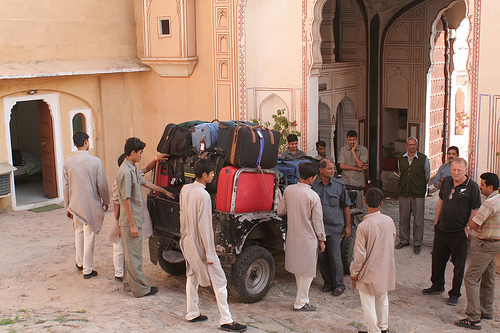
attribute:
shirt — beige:
[468, 188, 499, 239]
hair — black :
[192, 159, 213, 177]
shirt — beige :
[287, 185, 324, 265]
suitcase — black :
[217, 122, 281, 172]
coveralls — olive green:
[114, 161, 144, 288]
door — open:
[0, 85, 66, 206]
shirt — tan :
[262, 190, 341, 267]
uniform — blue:
[316, 174, 354, 285]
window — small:
[155, 15, 174, 40]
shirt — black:
[433, 177, 482, 246]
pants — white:
[181, 258, 228, 330]